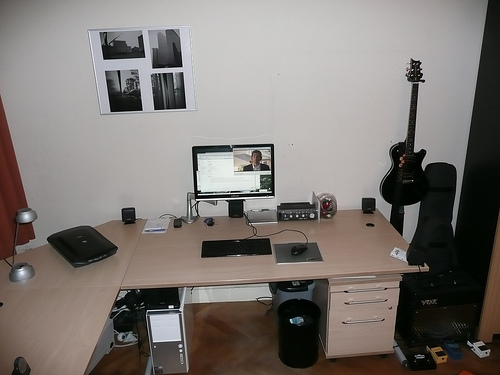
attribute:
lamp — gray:
[10, 207, 53, 277]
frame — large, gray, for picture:
[69, 10, 261, 125]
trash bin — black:
[276, 280, 329, 364]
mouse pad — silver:
[273, 241, 321, 263]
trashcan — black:
[274, 296, 325, 368]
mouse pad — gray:
[273, 242, 325, 265]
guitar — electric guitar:
[382, 53, 440, 214]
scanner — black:
[45, 221, 132, 276]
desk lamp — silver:
[9, 206, 39, 283]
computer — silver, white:
[141, 289, 196, 374]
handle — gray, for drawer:
[346, 295, 395, 307]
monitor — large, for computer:
[168, 133, 285, 227]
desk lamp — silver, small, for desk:
[6, 206, 40, 282]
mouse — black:
[291, 241, 306, 256]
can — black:
[262, 290, 329, 373]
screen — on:
[189, 146, 276, 199]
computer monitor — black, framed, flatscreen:
[192, 143, 270, 218]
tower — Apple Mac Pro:
[145, 285, 195, 373]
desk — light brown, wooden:
[134, 195, 391, 292]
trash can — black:
[277, 299, 319, 367]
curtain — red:
[0, 95, 40, 265]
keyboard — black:
[199, 238, 271, 257]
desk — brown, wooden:
[0, 210, 432, 375]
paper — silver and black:
[288, 312, 307, 329]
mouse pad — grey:
[273, 239, 294, 265]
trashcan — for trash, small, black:
[275, 298, 320, 366]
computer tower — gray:
[142, 288, 199, 373]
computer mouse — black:
[289, 239, 308, 258]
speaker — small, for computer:
[116, 205, 140, 226]